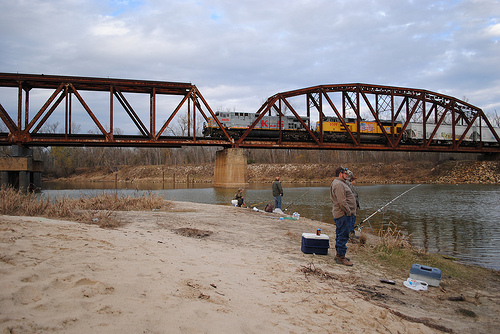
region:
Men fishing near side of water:
[330, 163, 424, 268]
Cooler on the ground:
[298, 230, 330, 255]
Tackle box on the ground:
[409, 257, 440, 289]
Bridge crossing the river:
[0, 80, 499, 190]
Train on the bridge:
[205, 110, 415, 137]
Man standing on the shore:
[271, 173, 285, 215]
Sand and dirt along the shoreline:
[0, 200, 498, 332]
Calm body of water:
[31, 178, 498, 268]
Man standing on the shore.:
[328, 163, 358, 268]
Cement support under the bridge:
[211, 144, 247, 191]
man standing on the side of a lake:
[331, 163, 358, 271]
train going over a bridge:
[199, 109, 496, 149]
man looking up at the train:
[272, 172, 285, 209]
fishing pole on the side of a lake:
[361, 178, 430, 230]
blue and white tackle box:
[408, 261, 443, 288]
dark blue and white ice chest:
[302, 223, 332, 255]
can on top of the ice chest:
[315, 226, 322, 235]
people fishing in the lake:
[346, 161, 363, 231]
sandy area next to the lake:
[0, 184, 498, 333]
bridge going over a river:
[0, 78, 496, 195]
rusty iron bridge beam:
[5, 65, 197, 98]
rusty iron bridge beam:
[14, 79, 39, 131]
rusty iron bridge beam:
[56, 81, 80, 138]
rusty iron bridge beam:
[105, 85, 119, 137]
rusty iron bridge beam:
[183, 93, 199, 145]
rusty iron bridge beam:
[3, 124, 234, 150]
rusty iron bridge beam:
[238, 133, 496, 155]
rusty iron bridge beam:
[277, 87, 310, 132]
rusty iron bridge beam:
[321, 84, 359, 140]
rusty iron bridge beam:
[377, 90, 401, 133]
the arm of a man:
[327, 173, 358, 216]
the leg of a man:
[324, 217, 359, 267]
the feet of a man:
[324, 240, 382, 300]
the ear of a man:
[327, 156, 357, 183]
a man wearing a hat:
[317, 154, 381, 225]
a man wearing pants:
[316, 194, 374, 277]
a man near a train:
[185, 60, 414, 257]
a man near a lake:
[216, 123, 410, 314]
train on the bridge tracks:
[196, 102, 498, 160]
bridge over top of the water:
[8, 61, 200, 210]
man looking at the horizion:
[330, 164, 358, 260]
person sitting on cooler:
[227, 186, 248, 211]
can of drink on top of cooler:
[297, 226, 333, 252]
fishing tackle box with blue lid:
[407, 261, 446, 285]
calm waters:
[46, 169, 215, 210]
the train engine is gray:
[199, 107, 314, 142]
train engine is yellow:
[314, 110, 405, 150]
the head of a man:
[331, 164, 358, 185]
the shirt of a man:
[320, 179, 357, 220]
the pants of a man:
[331, 213, 355, 253]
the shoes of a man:
[330, 251, 355, 273]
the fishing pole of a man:
[360, 175, 432, 238]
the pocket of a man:
[335, 211, 359, 223]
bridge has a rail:
[151, 87, 156, 140]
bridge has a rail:
[194, 89, 196, 136]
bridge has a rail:
[109, 84, 113, 134]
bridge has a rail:
[64, 85, 68, 137]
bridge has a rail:
[356, 89, 361, 139]